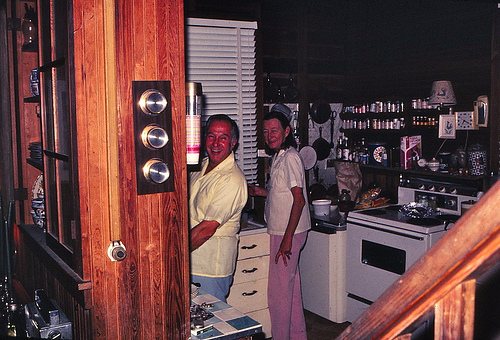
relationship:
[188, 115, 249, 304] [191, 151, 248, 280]
man with shirt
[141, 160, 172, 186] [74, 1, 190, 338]
dial on wall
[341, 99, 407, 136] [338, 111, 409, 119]
seasonings on shelf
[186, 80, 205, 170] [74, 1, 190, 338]
dispenser on wall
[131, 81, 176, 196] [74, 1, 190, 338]
barometer on wall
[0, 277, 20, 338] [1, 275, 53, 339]
trophies on floor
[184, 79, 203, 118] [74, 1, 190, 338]
holder on wall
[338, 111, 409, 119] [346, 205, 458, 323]
shelf next to stove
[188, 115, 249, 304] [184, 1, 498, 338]
man in kitchen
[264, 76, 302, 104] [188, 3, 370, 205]
pots on wall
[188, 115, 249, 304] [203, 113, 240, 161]
man has head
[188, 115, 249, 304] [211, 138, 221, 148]
man has nose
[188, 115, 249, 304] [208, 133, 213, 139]
man has eye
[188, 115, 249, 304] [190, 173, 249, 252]
man has arm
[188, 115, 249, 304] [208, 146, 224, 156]
man with mouth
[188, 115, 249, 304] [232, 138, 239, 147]
man has ear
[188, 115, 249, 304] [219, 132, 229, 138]
man has eyebrow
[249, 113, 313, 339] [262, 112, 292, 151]
woman has head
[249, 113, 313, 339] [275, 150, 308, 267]
woman has arm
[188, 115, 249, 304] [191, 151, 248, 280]
man wearing shirt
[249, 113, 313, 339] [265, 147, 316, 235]
woman wearing shirt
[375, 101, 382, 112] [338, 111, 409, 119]
spice on shelf